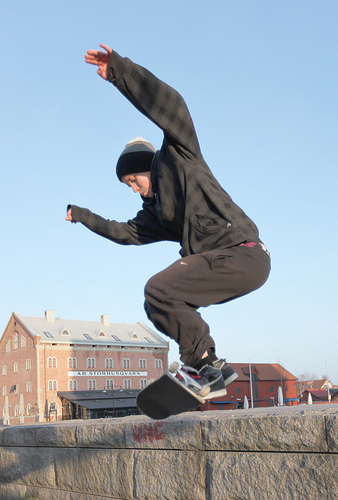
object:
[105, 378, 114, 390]
street lamp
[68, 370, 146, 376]
business name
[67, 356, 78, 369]
window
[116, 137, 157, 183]
beanie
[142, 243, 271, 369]
black pants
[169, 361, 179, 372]
wheel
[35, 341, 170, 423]
building side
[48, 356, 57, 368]
window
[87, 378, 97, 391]
window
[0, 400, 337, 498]
rock wall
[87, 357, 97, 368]
window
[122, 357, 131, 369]
window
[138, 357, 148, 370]
window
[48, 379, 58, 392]
window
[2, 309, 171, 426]
brick building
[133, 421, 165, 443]
graffiti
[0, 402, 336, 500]
fence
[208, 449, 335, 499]
stone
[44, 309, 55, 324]
chimney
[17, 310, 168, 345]
roof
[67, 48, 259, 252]
shirt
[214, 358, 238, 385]
sneakers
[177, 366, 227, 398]
sneakers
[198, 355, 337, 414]
building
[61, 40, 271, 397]
boy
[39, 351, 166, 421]
wall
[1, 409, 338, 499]
pattern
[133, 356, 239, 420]
trick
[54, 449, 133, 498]
stone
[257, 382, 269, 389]
items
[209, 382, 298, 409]
wall